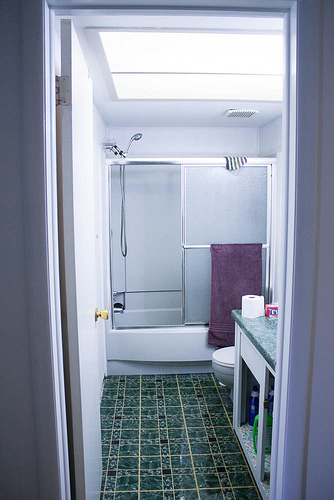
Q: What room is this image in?
A: It is at the bathroom.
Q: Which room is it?
A: It is a bathroom.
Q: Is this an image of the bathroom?
A: Yes, it is showing the bathroom.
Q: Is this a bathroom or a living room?
A: It is a bathroom.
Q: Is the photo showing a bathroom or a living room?
A: It is showing a bathroom.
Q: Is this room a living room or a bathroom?
A: It is a bathroom.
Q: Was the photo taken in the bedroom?
A: No, the picture was taken in the bathroom.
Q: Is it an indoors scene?
A: Yes, it is indoors.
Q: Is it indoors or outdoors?
A: It is indoors.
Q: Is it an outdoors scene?
A: No, it is indoors.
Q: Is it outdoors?
A: No, it is indoors.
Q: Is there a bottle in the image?
A: Yes, there is a bottle.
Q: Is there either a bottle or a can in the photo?
A: Yes, there is a bottle.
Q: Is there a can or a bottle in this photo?
A: Yes, there is a bottle.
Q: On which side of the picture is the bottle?
A: The bottle is on the right of the image.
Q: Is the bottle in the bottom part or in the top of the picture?
A: The bottle is in the bottom of the image.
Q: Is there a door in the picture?
A: Yes, there is a door.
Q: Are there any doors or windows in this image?
A: Yes, there is a door.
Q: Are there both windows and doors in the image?
A: No, there is a door but no windows.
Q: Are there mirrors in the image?
A: No, there are no mirrors.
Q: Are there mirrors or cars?
A: No, there are no mirrors or cars.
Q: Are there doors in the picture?
A: Yes, there is a door.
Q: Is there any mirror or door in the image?
A: Yes, there is a door.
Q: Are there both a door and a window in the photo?
A: No, there is a door but no windows.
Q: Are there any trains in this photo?
A: No, there are no trains.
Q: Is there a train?
A: No, there are no trains.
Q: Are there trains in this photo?
A: No, there are no trains.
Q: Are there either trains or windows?
A: No, there are no trains or windows.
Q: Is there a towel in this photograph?
A: Yes, there is a towel.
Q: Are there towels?
A: Yes, there is a towel.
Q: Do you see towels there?
A: Yes, there is a towel.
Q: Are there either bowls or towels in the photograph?
A: Yes, there is a towel.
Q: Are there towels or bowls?
A: Yes, there is a towel.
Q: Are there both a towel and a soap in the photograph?
A: No, there is a towel but no soaps.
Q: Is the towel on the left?
A: No, the towel is on the right of the image.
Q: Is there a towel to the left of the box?
A: Yes, there is a towel to the left of the box.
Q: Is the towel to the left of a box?
A: Yes, the towel is to the left of a box.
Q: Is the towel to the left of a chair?
A: No, the towel is to the left of a box.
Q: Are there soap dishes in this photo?
A: No, there are no soap dishes.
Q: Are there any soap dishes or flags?
A: No, there are no soap dishes or flags.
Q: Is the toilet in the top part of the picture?
A: No, the toilet is in the bottom of the image.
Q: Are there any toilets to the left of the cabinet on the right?
A: Yes, there is a toilet to the left of the cabinet.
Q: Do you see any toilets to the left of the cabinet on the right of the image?
A: Yes, there is a toilet to the left of the cabinet.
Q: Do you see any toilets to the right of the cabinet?
A: No, the toilet is to the left of the cabinet.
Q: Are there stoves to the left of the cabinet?
A: No, there is a toilet to the left of the cabinet.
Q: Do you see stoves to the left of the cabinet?
A: No, there is a toilet to the left of the cabinet.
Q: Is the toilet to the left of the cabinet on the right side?
A: Yes, the toilet is to the left of the cabinet.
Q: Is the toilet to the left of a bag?
A: No, the toilet is to the left of the cabinet.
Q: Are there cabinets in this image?
A: Yes, there is a cabinet.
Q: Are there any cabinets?
A: Yes, there is a cabinet.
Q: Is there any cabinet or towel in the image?
A: Yes, there is a cabinet.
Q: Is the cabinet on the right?
A: Yes, the cabinet is on the right of the image.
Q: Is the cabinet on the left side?
A: No, the cabinet is on the right of the image.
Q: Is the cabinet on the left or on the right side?
A: The cabinet is on the right of the image.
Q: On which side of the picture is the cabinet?
A: The cabinet is on the right of the image.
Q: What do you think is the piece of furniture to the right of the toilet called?
A: The piece of furniture is a cabinet.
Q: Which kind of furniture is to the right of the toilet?
A: The piece of furniture is a cabinet.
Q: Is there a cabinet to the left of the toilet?
A: No, the cabinet is to the right of the toilet.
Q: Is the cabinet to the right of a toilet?
A: Yes, the cabinet is to the right of a toilet.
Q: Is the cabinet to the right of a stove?
A: No, the cabinet is to the right of a toilet.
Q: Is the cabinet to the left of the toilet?
A: No, the cabinet is to the right of the toilet.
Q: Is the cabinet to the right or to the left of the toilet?
A: The cabinet is to the right of the toilet.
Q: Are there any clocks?
A: No, there are no clocks.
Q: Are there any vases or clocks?
A: No, there are no clocks or vases.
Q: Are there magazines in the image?
A: No, there are no magazines.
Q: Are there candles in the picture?
A: No, there are no candles.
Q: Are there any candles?
A: No, there are no candles.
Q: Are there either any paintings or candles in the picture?
A: No, there are no candles or paintings.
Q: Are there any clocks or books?
A: No, there are no clocks or books.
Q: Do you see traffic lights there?
A: No, there are no traffic lights.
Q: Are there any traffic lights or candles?
A: No, there are no traffic lights or candles.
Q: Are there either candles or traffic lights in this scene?
A: No, there are no traffic lights or candles.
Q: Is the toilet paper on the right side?
A: Yes, the toilet paper is on the right of the image.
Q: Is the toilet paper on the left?
A: No, the toilet paper is on the right of the image.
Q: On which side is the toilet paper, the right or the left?
A: The toilet paper is on the right of the image.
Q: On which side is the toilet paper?
A: The toilet paper is on the right of the image.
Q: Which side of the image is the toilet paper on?
A: The toilet paper is on the right of the image.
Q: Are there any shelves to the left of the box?
A: No, there is a toilet paper to the left of the box.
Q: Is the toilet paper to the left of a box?
A: Yes, the toilet paper is to the left of a box.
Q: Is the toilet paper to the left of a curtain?
A: No, the toilet paper is to the left of a box.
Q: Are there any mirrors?
A: No, there are no mirrors.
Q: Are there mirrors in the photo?
A: No, there are no mirrors.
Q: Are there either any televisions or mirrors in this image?
A: No, there are no mirrors or televisions.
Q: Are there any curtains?
A: No, there are no curtains.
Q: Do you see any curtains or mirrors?
A: No, there are no curtains or mirrors.